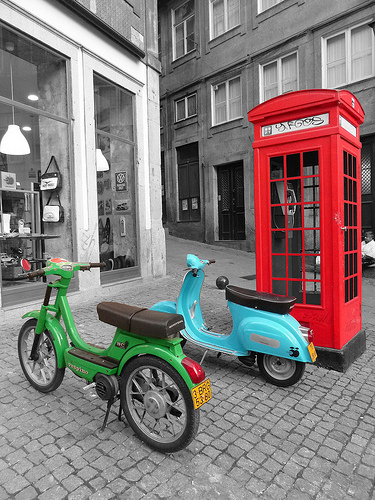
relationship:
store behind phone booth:
[0, 0, 374, 320] [247, 89, 366, 373]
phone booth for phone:
[247, 89, 366, 373] [271, 180, 296, 240]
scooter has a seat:
[15, 256, 212, 453] [96, 302, 186, 340]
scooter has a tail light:
[15, 256, 212, 453] [181, 357, 206, 384]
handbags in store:
[39, 155, 64, 223] [0, 0, 374, 320]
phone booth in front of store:
[247, 89, 366, 373] [0, 0, 374, 320]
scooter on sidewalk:
[15, 256, 212, 453] [1, 222, 374, 497]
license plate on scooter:
[191, 378, 213, 412] [15, 256, 212, 453]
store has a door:
[0, 0, 374, 320] [217, 161, 246, 241]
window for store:
[0, 19, 80, 307] [0, 0, 374, 320]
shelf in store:
[0, 182, 60, 268] [0, 0, 374, 320]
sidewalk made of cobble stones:
[1, 222, 374, 497] [0, 235, 375, 499]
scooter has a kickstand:
[15, 256, 212, 453] [99, 396, 124, 434]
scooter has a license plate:
[15, 256, 212, 453] [191, 378, 213, 412]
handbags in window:
[39, 155, 64, 223] [0, 19, 80, 307]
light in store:
[1, 40, 31, 156] [0, 0, 374, 320]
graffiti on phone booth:
[261, 115, 323, 135] [247, 89, 366, 373]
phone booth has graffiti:
[247, 89, 366, 373] [261, 115, 323, 135]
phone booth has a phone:
[247, 89, 366, 373] [271, 180, 296, 240]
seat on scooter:
[225, 285, 298, 316] [148, 254, 318, 386]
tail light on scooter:
[181, 357, 206, 384] [15, 256, 212, 453]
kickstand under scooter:
[99, 396, 124, 434] [15, 256, 212, 453]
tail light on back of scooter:
[181, 357, 206, 384] [15, 256, 212, 453]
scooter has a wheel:
[15, 256, 212, 453] [118, 355, 200, 454]